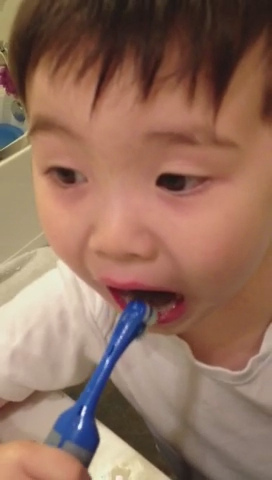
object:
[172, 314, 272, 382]
collar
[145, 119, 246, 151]
eye brows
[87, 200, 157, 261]
nose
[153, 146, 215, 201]
eye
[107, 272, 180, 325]
teeth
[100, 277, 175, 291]
lip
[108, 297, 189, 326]
lip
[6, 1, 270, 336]
head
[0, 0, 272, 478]
baby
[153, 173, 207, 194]
black white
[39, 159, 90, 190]
eye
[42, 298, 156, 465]
toothbrush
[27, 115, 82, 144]
eyebrow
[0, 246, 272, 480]
baby tee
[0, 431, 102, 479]
hand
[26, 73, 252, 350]
face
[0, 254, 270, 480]
shirt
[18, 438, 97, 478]
finger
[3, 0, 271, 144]
hair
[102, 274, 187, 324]
mouth